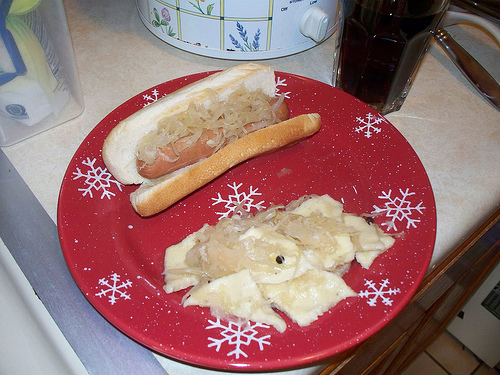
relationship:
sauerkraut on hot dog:
[155, 93, 262, 132] [97, 50, 325, 223]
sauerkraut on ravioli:
[194, 217, 256, 271] [180, 264, 292, 335]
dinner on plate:
[106, 64, 394, 324] [28, 58, 441, 368]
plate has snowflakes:
[28, 58, 441, 368] [369, 181, 432, 241]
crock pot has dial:
[139, 2, 343, 61] [301, 3, 331, 46]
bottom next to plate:
[333, 0, 453, 116] [28, 58, 441, 368]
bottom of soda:
[333, 0, 453, 116] [361, 8, 417, 75]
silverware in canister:
[17, 9, 72, 102] [2, 5, 87, 155]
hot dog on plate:
[97, 50, 325, 223] [28, 58, 441, 368]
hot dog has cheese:
[97, 50, 325, 223] [195, 93, 267, 124]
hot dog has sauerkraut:
[97, 50, 325, 223] [155, 93, 262, 132]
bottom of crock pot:
[144, 25, 288, 62] [139, 2, 343, 61]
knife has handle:
[447, 28, 499, 109] [459, 58, 499, 107]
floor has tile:
[406, 315, 497, 374] [436, 334, 479, 369]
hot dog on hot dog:
[97, 50, 325, 223] [97, 50, 325, 223]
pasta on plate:
[167, 194, 396, 334] [28, 58, 441, 368]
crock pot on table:
[139, 2, 343, 61] [13, 13, 499, 340]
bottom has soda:
[333, 0, 453, 116] [361, 8, 417, 75]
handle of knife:
[459, 58, 499, 107] [447, 28, 499, 109]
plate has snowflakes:
[28, 58, 441, 368] [91, 268, 136, 310]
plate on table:
[28, 58, 441, 368] [13, 13, 499, 340]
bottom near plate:
[333, 0, 453, 116] [28, 58, 441, 368]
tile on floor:
[436, 334, 479, 369] [406, 315, 497, 374]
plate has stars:
[28, 58, 441, 368] [87, 165, 110, 193]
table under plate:
[13, 13, 499, 340] [28, 58, 441, 368]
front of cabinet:
[410, 255, 496, 340] [337, 220, 499, 367]